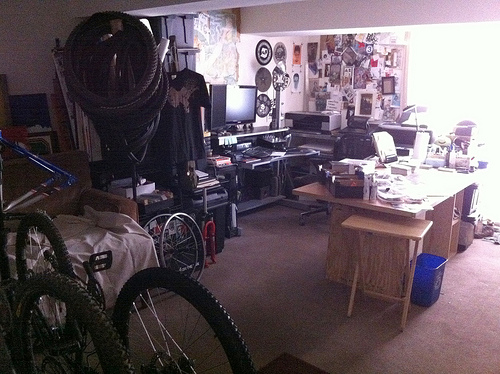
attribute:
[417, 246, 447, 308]
waste basket — blue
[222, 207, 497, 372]
carpet — beige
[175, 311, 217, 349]
spoke — metal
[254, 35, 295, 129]
pictures — round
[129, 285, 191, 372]
spoke — metal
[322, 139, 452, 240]
counter — cluttered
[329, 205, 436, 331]
table — wooden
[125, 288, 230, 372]
metalspoke — metal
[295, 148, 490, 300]
table — wooden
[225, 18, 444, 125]
wall — cluttered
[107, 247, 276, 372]
tire — metal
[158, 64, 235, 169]
shirt — black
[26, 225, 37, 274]
spoke — metal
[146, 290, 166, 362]
spoke — metal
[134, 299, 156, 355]
spoke — metal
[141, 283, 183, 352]
spoke — metal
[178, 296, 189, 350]
spoke — metal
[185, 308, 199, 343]
spoke — metal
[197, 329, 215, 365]
spoke — metal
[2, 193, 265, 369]
tires — black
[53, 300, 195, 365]
spokes — metal